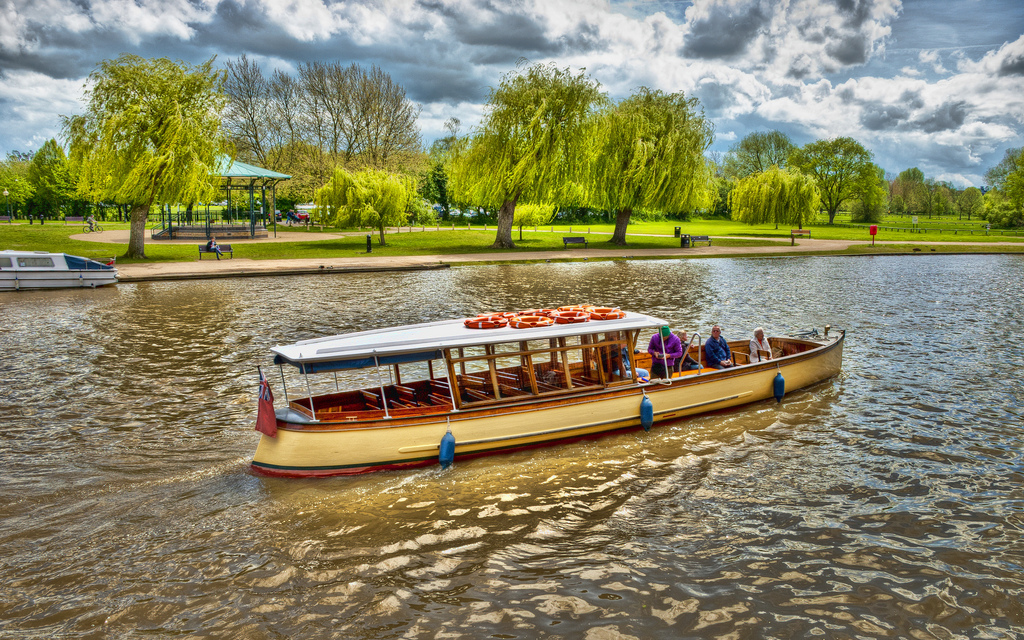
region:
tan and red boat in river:
[199, 305, 899, 457]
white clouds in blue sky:
[903, 74, 964, 116]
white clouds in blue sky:
[917, 61, 975, 118]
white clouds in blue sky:
[742, 63, 815, 106]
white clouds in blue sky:
[574, 24, 644, 73]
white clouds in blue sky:
[411, 33, 481, 65]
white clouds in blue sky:
[19, 12, 61, 51]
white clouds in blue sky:
[404, 39, 450, 68]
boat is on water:
[262, 265, 844, 512]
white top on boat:
[320, 280, 576, 402]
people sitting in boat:
[645, 290, 783, 388]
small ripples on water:
[817, 425, 941, 638]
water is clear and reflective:
[722, 470, 944, 616]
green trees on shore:
[162, 19, 878, 250]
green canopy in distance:
[181, 139, 280, 204]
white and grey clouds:
[598, 0, 971, 133]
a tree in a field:
[56, 47, 241, 263]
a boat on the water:
[259, 291, 847, 456]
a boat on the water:
[3, 247, 121, 298]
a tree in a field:
[335, 154, 416, 240]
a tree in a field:
[453, 47, 593, 244]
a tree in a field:
[598, 70, 697, 258]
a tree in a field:
[724, 165, 810, 243]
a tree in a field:
[791, 117, 867, 226]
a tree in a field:
[272, 48, 459, 170]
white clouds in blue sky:
[836, 40, 874, 75]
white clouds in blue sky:
[713, 25, 780, 74]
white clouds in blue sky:
[611, 37, 663, 75]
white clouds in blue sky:
[450, 54, 508, 80]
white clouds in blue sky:
[336, 22, 423, 60]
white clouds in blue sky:
[29, 37, 90, 92]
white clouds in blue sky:
[883, 19, 953, 97]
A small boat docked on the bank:
[6, 251, 118, 284]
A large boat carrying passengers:
[250, 299, 846, 477]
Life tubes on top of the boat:
[468, 296, 625, 332]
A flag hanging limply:
[250, 355, 280, 438]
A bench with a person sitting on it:
[194, 233, 237, 262]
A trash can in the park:
[671, 224, 684, 240]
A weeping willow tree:
[591, 88, 718, 267]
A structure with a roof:
[147, 145, 285, 241]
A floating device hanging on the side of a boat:
[434, 429, 461, 471]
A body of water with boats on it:
[9, 255, 1016, 638]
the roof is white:
[273, 296, 656, 364]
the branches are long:
[443, 62, 599, 208]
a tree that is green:
[441, 83, 677, 214]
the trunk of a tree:
[471, 189, 538, 267]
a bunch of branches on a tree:
[292, 75, 417, 151]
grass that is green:
[280, 233, 329, 273]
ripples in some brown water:
[523, 455, 736, 610]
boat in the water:
[220, 307, 863, 424]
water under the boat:
[662, 475, 814, 586]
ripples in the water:
[539, 492, 752, 609]